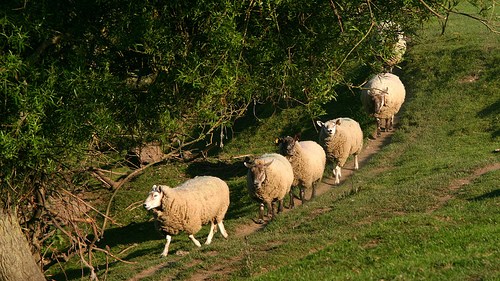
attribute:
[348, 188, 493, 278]
grass — green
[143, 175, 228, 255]
sheep — big, white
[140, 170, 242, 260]
sheep — waling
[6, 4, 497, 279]
grass — white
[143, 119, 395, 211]
sheep — big, white, walking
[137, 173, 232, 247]
sheep — white , Big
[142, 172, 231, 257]
white sheep — big, walking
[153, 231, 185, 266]
leg — white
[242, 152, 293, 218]
sheep — dark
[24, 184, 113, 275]
twigs/tree — dry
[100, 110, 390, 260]
sheep — walking, big, white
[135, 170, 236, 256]
sheep — big, white, walking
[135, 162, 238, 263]
sheep — big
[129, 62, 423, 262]
sheep — white